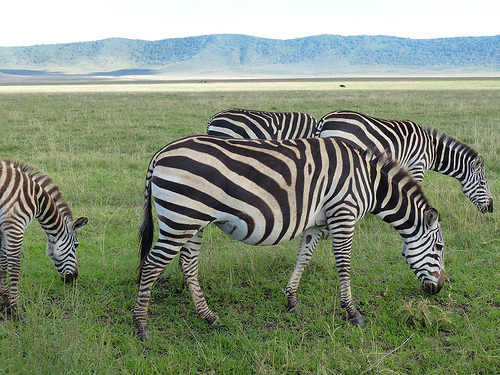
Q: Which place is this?
A: It is a field.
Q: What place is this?
A: It is a field.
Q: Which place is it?
A: It is a field.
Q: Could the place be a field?
A: Yes, it is a field.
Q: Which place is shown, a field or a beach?
A: It is a field.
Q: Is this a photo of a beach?
A: No, the picture is showing a field.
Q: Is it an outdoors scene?
A: Yes, it is outdoors.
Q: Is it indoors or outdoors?
A: It is outdoors.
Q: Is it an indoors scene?
A: No, it is outdoors.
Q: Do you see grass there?
A: Yes, there is grass.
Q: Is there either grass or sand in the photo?
A: Yes, there is grass.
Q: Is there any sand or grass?
A: Yes, there is grass.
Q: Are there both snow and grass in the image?
A: No, there is grass but no snow.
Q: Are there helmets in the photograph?
A: No, there are no helmets.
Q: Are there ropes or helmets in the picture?
A: No, there are no helmets or ropes.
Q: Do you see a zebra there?
A: Yes, there is a zebra.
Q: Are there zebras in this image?
A: Yes, there is a zebra.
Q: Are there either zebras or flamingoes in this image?
A: Yes, there is a zebra.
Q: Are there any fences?
A: No, there are no fences.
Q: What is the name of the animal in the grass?
A: The animal is a zebra.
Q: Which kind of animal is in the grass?
A: The animal is a zebra.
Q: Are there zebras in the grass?
A: Yes, there is a zebra in the grass.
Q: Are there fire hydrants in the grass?
A: No, there is a zebra in the grass.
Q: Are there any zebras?
A: Yes, there is a zebra.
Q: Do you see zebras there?
A: Yes, there is a zebra.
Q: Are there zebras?
A: Yes, there is a zebra.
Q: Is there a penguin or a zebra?
A: Yes, there is a zebra.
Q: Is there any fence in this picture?
A: No, there are no fences.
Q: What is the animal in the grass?
A: The animal is a zebra.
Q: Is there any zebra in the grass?
A: Yes, there is a zebra in the grass.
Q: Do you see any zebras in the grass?
A: Yes, there is a zebra in the grass.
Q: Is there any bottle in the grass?
A: No, there is a zebra in the grass.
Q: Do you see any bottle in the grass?
A: No, there is a zebra in the grass.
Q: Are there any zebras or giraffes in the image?
A: Yes, there is a zebra.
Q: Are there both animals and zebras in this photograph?
A: Yes, there are both a zebra and an animal.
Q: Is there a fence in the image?
A: No, there are no fences.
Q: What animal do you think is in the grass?
A: The zebra is in the grass.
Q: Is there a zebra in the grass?
A: Yes, there is a zebra in the grass.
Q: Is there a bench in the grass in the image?
A: No, there is a zebra in the grass.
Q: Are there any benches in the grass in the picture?
A: No, there is a zebra in the grass.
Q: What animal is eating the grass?
A: The zebra is eating the grass.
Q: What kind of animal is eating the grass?
A: The animal is a zebra.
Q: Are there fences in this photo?
A: No, there are no fences.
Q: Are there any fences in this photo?
A: No, there are no fences.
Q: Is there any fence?
A: No, there are no fences.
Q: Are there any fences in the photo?
A: No, there are no fences.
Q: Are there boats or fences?
A: No, there are no fences or boats.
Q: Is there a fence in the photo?
A: No, there are no fences.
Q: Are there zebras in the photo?
A: Yes, there is a zebra.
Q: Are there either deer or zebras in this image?
A: Yes, there is a zebra.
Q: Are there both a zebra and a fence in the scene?
A: No, there is a zebra but no fences.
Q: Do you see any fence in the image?
A: No, there are no fences.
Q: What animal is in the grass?
A: The animal is a zebra.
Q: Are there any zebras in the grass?
A: Yes, there is a zebra in the grass.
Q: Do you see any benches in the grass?
A: No, there is a zebra in the grass.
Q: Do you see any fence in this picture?
A: No, there are no fences.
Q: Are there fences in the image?
A: No, there are no fences.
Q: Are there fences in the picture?
A: No, there are no fences.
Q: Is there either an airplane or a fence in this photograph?
A: No, there are no fences or airplanes.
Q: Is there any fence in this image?
A: No, there are no fences.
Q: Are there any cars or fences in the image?
A: No, there are no fences or cars.